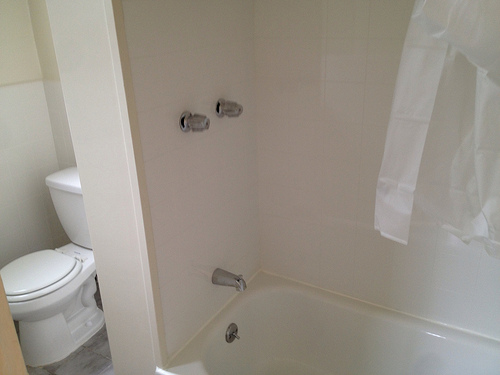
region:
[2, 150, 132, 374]
This is a toilet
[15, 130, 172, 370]
This is a toilet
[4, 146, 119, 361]
This is a toilet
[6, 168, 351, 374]
This is a toilet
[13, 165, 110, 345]
This is a toilet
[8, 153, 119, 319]
This is a toilet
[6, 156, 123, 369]
This is a toilet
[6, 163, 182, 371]
This is a toilet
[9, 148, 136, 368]
This is a toilet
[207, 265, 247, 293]
a silver bathtub spout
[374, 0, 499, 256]
a white shower curtain that is torn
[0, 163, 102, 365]
a white toilet stool with the lid shut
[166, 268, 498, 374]
a white bath tub with white grouting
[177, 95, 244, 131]
two silver faucet handles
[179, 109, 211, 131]
one silver faucet handle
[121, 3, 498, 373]
a shower stall with white tile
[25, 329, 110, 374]
white and grey marbled flooring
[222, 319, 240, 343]
a silver bathtub drain with the handle aimed down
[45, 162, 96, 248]
a white toilet tank with a white lid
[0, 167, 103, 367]
a white toilet in a bathroom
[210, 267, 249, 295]
the faucet of a bathtub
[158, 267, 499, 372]
a white bathtub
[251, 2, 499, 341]
a white tile shower wall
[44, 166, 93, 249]
the water tank on the back of a toilet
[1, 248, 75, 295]
a shut toilet lid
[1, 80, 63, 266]
a white wall beside a toilet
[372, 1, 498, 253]
a clear plastic shower curtain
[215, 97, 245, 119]
the cold water knob in a shower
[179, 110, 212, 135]
the hot water knob in a shower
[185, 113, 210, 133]
the knob of the shower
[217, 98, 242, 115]
the knob of the shower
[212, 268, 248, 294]
the silver faucet of the tub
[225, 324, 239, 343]
the silver stopper of the tub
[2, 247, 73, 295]
the white toilet seat cover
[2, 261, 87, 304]
the white toilet seat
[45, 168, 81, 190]
the white toilet tank cover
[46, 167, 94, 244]
the white toilet tank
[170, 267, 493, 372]
the white tub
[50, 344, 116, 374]
the white tile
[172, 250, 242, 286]
faucet of the bath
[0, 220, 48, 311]
lid of the toilet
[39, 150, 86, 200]
tank of the toilet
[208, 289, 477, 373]
rim of the tub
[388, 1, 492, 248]
curtain of the shower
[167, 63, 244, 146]
knobs on the wall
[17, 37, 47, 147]
tiles on the wall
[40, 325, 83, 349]
the toilet is white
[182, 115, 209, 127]
the knob is silver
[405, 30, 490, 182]
the curtain is clear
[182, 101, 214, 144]
hot water handle on shower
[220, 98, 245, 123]
cold water handle on shower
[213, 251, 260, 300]
shiny silver faucet in shower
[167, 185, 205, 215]
pale tiles on shower wall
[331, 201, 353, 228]
pale tiles on shower wall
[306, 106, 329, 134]
pale tiles on shower wall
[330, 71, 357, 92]
pale tiles on shower wall